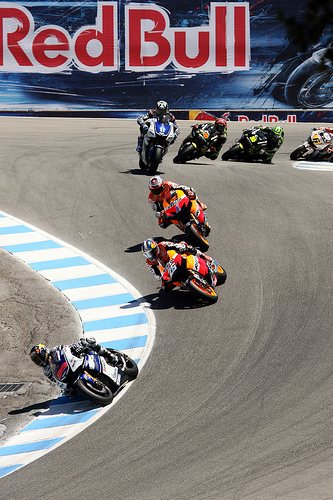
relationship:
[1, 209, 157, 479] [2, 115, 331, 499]
stripes on track